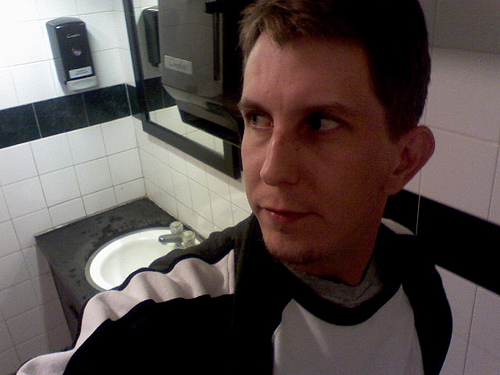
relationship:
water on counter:
[100, 216, 116, 231] [44, 198, 216, 299]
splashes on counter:
[99, 211, 129, 224] [44, 198, 216, 299]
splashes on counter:
[92, 214, 117, 234] [35, 192, 198, 292]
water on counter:
[94, 212, 114, 230] [35, 192, 198, 292]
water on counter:
[89, 220, 108, 234] [45, 197, 200, 298]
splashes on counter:
[79, 207, 129, 230] [45, 197, 200, 298]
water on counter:
[59, 218, 127, 234] [40, 207, 200, 293]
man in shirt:
[15, 8, 455, 375] [11, 213, 455, 371]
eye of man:
[297, 111, 354, 133] [69, 9, 464, 352]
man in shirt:
[69, 9, 464, 352] [20, 194, 460, 366]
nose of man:
[258, 120, 300, 187] [15, 8, 455, 375]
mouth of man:
[252, 200, 319, 222] [15, 8, 455, 375]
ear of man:
[382, 124, 436, 197] [15, 8, 455, 375]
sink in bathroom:
[85, 226, 205, 293] [4, 0, 498, 372]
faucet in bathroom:
[157, 223, 195, 247] [4, 0, 498, 372]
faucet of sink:
[157, 223, 195, 247] [85, 226, 205, 293]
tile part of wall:
[67, 156, 115, 196] [2, 0, 147, 374]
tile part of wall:
[421, 43, 498, 142] [128, 7, 498, 372]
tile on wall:
[100, 113, 137, 153] [2, 0, 147, 374]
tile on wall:
[65, 124, 109, 163] [2, 0, 147, 374]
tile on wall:
[28, 132, 74, 177] [2, 0, 147, 374]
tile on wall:
[0, 142, 46, 187] [2, 0, 147, 374]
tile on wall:
[102, 147, 144, 188] [2, 0, 147, 374]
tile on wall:
[72, 157, 114, 197] [2, 0, 147, 374]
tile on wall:
[38, 164, 85, 206] [2, 0, 147, 374]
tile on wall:
[2, 174, 50, 217] [2, 0, 147, 374]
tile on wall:
[115, 177, 146, 207] [2, 0, 147, 374]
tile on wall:
[83, 189, 117, 214] [2, 0, 147, 374]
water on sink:
[61, 210, 171, 259] [31, 196, 206, 346]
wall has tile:
[2, 0, 147, 374] [32, 94, 92, 141]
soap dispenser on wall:
[46, 15, 101, 95] [2, 0, 147, 374]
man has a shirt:
[15, 8, 455, 375] [11, 213, 455, 371]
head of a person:
[236, 0, 437, 267] [14, 0, 456, 373]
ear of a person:
[382, 124, 436, 197] [14, 0, 456, 373]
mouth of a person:
[257, 202, 319, 226] [14, 0, 456, 373]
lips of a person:
[261, 203, 310, 223] [14, 0, 456, 373]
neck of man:
[283, 193, 383, 283] [15, 8, 455, 375]